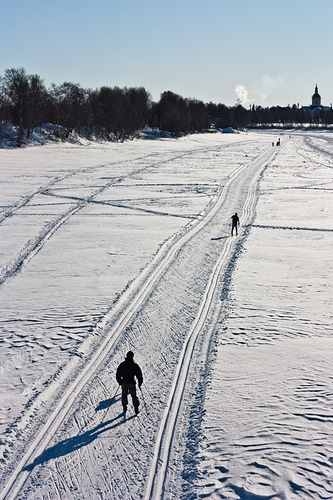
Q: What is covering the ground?
A: Snow.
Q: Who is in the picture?
A: Skiers.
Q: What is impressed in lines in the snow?
A: Tracks.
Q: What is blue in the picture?
A: The sky.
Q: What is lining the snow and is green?
A: Trees.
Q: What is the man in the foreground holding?
A: Poles.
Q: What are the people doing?
A: Skiing.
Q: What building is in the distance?
A: A church.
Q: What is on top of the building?
A: A spire.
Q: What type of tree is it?
A: Full and brown trees.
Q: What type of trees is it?
A: It's brown trees.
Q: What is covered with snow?
A: A large field.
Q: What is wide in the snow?
A: A wide track.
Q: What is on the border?
A: The trees are.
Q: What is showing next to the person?
A: The person's shadow.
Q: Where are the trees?
A: In the background.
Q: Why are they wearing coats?
A: It is cold.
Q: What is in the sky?
A: Clouds.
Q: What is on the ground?
A: Snow.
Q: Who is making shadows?
A: The people.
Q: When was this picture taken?
A: Winter.